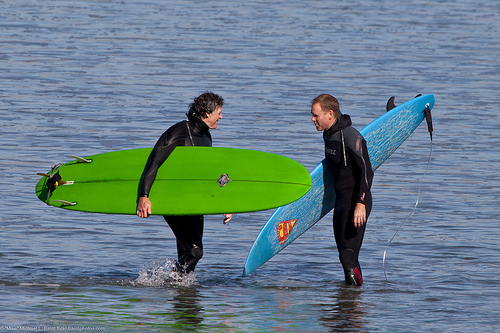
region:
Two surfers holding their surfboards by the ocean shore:
[30, 88, 440, 299]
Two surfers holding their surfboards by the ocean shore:
[26, 88, 440, 295]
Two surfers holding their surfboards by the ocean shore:
[32, 87, 441, 309]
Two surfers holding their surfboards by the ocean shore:
[30, 81, 444, 301]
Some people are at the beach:
[0, 20, 491, 307]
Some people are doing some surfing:
[25, 20, 496, 315]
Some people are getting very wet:
[30, 45, 471, 290]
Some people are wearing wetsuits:
[23, 31, 470, 324]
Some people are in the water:
[7, 33, 468, 298]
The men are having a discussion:
[25, 28, 481, 299]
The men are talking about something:
[22, 26, 493, 327]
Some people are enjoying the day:
[31, 44, 462, 280]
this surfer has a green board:
[33, 69, 291, 301]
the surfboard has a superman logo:
[234, 99, 436, 295]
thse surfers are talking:
[127, 61, 392, 313]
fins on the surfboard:
[14, 138, 99, 224]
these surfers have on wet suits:
[125, 81, 384, 306]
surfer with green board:
[157, 76, 241, 293]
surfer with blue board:
[311, 81, 398, 286]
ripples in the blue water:
[410, 269, 447, 289]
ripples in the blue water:
[21, 253, 76, 298]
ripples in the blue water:
[340, 21, 398, 61]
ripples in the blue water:
[111, 48, 151, 82]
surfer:
[120, 83, 245, 273]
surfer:
[304, 75, 385, 309]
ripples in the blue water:
[45, 23, 97, 61]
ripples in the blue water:
[404, 258, 441, 288]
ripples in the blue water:
[400, 15, 450, 52]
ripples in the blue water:
[454, 235, 498, 272]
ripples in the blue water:
[262, 18, 322, 73]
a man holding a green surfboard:
[35, 84, 312, 220]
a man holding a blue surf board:
[246, 77, 432, 289]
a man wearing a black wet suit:
[325, 123, 375, 294]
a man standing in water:
[300, 87, 368, 306]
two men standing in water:
[147, 67, 392, 292]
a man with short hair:
[312, 90, 338, 119]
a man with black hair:
[192, 85, 224, 114]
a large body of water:
[31, 6, 447, 93]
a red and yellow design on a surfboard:
[267, 212, 304, 244]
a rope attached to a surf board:
[375, 115, 432, 277]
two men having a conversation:
[137, 91, 374, 285]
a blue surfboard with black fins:
[242, 92, 435, 275]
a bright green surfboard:
[36, 145, 312, 215]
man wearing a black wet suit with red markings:
[310, 93, 373, 288]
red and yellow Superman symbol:
[275, 218, 298, 243]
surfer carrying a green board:
[34, 93, 311, 274]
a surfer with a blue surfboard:
[244, 94, 435, 284]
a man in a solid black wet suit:
[135, 91, 225, 275]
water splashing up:
[134, 258, 202, 288]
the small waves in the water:
[408, 249, 470, 299]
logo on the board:
[269, 215, 299, 240]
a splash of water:
[147, 270, 185, 290]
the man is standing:
[309, 87, 381, 287]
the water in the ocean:
[357, 37, 405, 64]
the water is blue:
[421, 268, 453, 313]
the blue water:
[429, 245, 494, 297]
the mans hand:
[352, 203, 367, 223]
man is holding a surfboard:
[121, 155, 178, 214]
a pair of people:
[128, 70, 388, 302]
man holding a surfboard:
[28, 62, 313, 267]